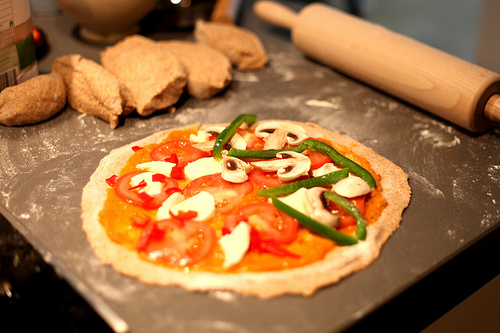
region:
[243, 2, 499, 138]
A WOODEN ROLLING PIN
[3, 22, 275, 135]
FIVE LUMPS OF PIZZA DOUGH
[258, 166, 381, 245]
SWEET GREEN PEPPER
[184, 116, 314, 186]
SLICES OF MUSHROOMS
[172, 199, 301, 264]
SLICES OF TOMATOES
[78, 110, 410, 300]
AN UNCOOKED PIZZA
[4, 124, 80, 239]
FLOUR ON A METAL SURFACE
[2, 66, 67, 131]
A LUMP OF PIZZA DOUGH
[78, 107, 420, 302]
A PHOTO OF AN UNCOOKED PIZZA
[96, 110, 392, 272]
GREEN PEPPER, TOMATO AND MUSHROOMS ON A PIZZA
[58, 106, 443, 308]
Pizza is in the foreground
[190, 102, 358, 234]
Pizza has mushrooms as toppings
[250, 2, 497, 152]
A dough roller in the background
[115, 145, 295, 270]
Pizza has tomato as a topping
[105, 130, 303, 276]
Tomatos are red in color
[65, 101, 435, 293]
Pizza in the foreground is uncooked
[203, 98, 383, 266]
Pizza has green peppers as a topping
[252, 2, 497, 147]
Roller is made out of wood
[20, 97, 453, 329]
Pizza is on a gray surface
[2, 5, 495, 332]
Photo was taken indoors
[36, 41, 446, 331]
an uncooked pizza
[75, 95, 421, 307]
uncooked pizza on table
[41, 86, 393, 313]
douch with red sauce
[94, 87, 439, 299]
douch with mushroom on top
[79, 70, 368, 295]
pizza with tomatos mushrooms and peppers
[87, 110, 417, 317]
a pizza with bell peppers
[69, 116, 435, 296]
an uncooked pizza with three toppings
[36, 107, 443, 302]
an uncooked pizza with sauce and vegetables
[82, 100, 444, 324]
vegetables on a pizza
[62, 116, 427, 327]
toppings on a pizza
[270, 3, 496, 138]
a wooden rolling pin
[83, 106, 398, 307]
an uncooked pizza on a counter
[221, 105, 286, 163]
slices of a green pepper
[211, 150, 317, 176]
slices of mushroom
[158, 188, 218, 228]
bits of mozzarella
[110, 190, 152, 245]
slices of tomatoes on a pizza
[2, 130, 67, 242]
white flour on a counter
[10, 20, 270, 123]
pizza dough on a counter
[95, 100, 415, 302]
a pizza with tomatoes, green peppers and mushrooms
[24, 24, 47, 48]
a red light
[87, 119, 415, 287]
The pizza is round.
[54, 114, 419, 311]
The pizza is uncooked.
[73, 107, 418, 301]
The pizza is small.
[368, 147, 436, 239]
The crust is white.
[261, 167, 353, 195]
The peppers are green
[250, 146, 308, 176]
The mushrooms are white.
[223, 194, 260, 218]
The sauce is red.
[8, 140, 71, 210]
Flour is on the table.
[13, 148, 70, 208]
The flour is white.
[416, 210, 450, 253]
The table is gray.